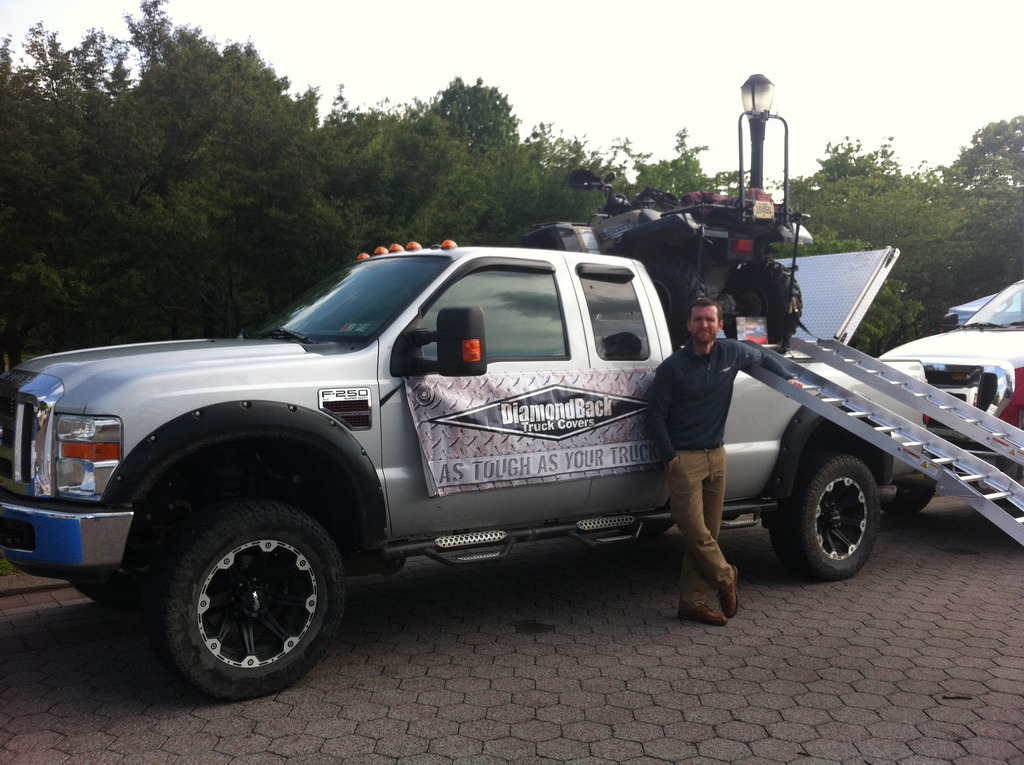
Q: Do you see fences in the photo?
A: No, there are no fences.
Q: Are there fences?
A: No, there are no fences.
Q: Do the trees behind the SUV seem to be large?
A: Yes, the trees are large.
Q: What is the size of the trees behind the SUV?
A: The trees are large.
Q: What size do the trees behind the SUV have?
A: The trees have large size.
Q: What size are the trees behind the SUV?
A: The trees are large.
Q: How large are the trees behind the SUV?
A: The trees are large.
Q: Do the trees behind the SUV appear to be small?
A: No, the trees are large.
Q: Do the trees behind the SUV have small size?
A: No, the trees are large.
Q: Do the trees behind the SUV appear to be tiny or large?
A: The trees are large.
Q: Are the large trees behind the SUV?
A: Yes, the trees are behind the SUV.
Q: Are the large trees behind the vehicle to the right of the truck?
A: Yes, the trees are behind the SUV.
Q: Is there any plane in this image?
A: No, there are no airplanes.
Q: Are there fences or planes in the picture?
A: No, there are no planes or fences.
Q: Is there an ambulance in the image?
A: No, there are no ambulances.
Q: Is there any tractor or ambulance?
A: No, there are no ambulances or tractors.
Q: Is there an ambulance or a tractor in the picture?
A: No, there are no ambulances or tractors.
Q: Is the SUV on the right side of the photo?
A: Yes, the SUV is on the right of the image.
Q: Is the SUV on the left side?
A: No, the SUV is on the right of the image.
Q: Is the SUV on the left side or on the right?
A: The SUV is on the right of the image.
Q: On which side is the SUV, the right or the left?
A: The SUV is on the right of the image.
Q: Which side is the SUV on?
A: The SUV is on the right of the image.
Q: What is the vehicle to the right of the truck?
A: The vehicle is a SUV.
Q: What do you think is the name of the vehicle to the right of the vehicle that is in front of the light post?
A: The vehicle is a SUV.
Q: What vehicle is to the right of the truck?
A: The vehicle is a SUV.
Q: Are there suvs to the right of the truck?
A: Yes, there is a SUV to the right of the truck.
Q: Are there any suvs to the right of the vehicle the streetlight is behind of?
A: Yes, there is a SUV to the right of the truck.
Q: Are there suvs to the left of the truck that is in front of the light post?
A: No, the SUV is to the right of the truck.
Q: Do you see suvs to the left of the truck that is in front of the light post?
A: No, the SUV is to the right of the truck.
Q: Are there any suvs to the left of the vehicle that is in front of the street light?
A: No, the SUV is to the right of the truck.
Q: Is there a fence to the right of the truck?
A: No, there is a SUV to the right of the truck.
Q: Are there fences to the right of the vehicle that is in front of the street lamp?
A: No, there is a SUV to the right of the truck.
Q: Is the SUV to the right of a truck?
A: Yes, the SUV is to the right of a truck.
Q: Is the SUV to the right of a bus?
A: No, the SUV is to the right of a truck.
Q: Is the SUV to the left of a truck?
A: No, the SUV is to the right of a truck.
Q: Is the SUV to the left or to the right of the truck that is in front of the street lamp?
A: The SUV is to the right of the truck.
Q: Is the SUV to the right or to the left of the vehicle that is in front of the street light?
A: The SUV is to the right of the truck.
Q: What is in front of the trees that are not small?
A: The SUV is in front of the trees.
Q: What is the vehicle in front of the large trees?
A: The vehicle is a SUV.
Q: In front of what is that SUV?
A: The SUV is in front of the trees.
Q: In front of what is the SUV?
A: The SUV is in front of the trees.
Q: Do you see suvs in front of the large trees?
A: Yes, there is a SUV in front of the trees.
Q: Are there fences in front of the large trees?
A: No, there is a SUV in front of the trees.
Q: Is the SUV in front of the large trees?
A: Yes, the SUV is in front of the trees.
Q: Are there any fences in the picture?
A: No, there are no fences.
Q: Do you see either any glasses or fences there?
A: No, there are no fences or glasses.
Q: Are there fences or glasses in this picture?
A: No, there are no fences or glasses.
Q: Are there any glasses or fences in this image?
A: No, there are no fences or glasses.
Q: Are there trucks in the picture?
A: Yes, there is a truck.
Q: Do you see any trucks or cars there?
A: Yes, there is a truck.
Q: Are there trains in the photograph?
A: No, there are no trains.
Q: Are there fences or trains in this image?
A: No, there are no trains or fences.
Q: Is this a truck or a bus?
A: This is a truck.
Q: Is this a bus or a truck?
A: This is a truck.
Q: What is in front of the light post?
A: The truck is in front of the light post.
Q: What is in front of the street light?
A: The truck is in front of the light post.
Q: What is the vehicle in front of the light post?
A: The vehicle is a truck.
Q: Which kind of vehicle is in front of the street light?
A: The vehicle is a truck.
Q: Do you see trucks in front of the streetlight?
A: Yes, there is a truck in front of the streetlight.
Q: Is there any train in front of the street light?
A: No, there is a truck in front of the street light.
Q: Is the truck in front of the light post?
A: Yes, the truck is in front of the light post.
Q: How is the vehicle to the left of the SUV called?
A: The vehicle is a truck.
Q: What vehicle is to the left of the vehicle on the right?
A: The vehicle is a truck.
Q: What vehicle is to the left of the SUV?
A: The vehicle is a truck.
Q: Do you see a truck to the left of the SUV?
A: Yes, there is a truck to the left of the SUV.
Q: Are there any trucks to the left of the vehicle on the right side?
A: Yes, there is a truck to the left of the SUV.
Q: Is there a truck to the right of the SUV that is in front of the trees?
A: No, the truck is to the left of the SUV.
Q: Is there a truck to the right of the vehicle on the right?
A: No, the truck is to the left of the SUV.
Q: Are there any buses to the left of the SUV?
A: No, there is a truck to the left of the SUV.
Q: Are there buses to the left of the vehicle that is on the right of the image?
A: No, there is a truck to the left of the SUV.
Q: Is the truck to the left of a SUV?
A: Yes, the truck is to the left of a SUV.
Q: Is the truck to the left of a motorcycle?
A: No, the truck is to the left of a SUV.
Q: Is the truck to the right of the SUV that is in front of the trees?
A: No, the truck is to the left of the SUV.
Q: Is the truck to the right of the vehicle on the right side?
A: No, the truck is to the left of the SUV.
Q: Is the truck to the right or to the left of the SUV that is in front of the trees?
A: The truck is to the left of the SUV.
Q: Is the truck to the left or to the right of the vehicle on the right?
A: The truck is to the left of the SUV.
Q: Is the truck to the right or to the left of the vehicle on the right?
A: The truck is to the left of the SUV.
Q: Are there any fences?
A: No, there are no fences.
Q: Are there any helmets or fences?
A: No, there are no fences or helmets.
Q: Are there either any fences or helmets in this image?
A: No, there are no fences or helmets.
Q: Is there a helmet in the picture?
A: No, there are no helmets.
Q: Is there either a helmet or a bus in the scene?
A: No, there are no helmets or buses.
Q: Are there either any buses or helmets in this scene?
A: No, there are no helmets or buses.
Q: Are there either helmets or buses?
A: No, there are no helmets or buses.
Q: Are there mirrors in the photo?
A: Yes, there is a mirror.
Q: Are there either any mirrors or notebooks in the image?
A: Yes, there is a mirror.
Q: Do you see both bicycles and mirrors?
A: No, there is a mirror but no bikes.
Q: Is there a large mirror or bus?
A: Yes, there is a large mirror.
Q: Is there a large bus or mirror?
A: Yes, there is a large mirror.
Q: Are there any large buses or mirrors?
A: Yes, there is a large mirror.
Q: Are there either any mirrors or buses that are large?
A: Yes, the mirror is large.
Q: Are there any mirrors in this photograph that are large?
A: Yes, there is a large mirror.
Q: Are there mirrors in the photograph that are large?
A: Yes, there is a mirror that is large.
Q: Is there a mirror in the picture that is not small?
A: Yes, there is a large mirror.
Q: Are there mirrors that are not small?
A: Yes, there is a large mirror.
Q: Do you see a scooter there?
A: No, there are no scooters.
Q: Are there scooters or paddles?
A: No, there are no scooters or paddles.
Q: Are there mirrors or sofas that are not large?
A: No, there is a mirror but it is large.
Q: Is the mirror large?
A: Yes, the mirror is large.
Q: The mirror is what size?
A: The mirror is large.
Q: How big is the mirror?
A: The mirror is large.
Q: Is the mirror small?
A: No, the mirror is large.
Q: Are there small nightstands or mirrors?
A: No, there is a mirror but it is large.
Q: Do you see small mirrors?
A: No, there is a mirror but it is large.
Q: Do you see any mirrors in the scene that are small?
A: No, there is a mirror but it is large.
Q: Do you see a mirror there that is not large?
A: No, there is a mirror but it is large.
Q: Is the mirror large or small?
A: The mirror is large.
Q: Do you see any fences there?
A: No, there are no fences.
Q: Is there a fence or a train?
A: No, there are no fences or trains.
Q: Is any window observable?
A: Yes, there is a window.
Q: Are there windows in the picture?
A: Yes, there is a window.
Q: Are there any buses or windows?
A: Yes, there is a window.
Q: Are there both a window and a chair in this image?
A: No, there is a window but no chairs.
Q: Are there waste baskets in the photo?
A: No, there are no waste baskets.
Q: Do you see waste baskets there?
A: No, there are no waste baskets.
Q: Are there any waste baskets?
A: No, there are no waste baskets.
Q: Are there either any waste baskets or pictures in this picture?
A: No, there are no waste baskets or pictures.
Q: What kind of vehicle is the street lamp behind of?
A: The street lamp is behind the truck.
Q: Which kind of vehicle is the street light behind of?
A: The street lamp is behind the truck.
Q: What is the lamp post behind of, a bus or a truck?
A: The lamp post is behind a truck.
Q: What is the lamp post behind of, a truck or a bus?
A: The lamp post is behind a truck.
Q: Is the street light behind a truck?
A: Yes, the street light is behind a truck.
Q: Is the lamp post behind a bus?
A: No, the lamp post is behind a truck.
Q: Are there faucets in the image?
A: No, there are no faucets.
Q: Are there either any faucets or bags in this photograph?
A: No, there are no faucets or bags.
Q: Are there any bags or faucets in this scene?
A: No, there are no faucets or bags.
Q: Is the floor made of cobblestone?
A: Yes, the floor is made of cobblestone.